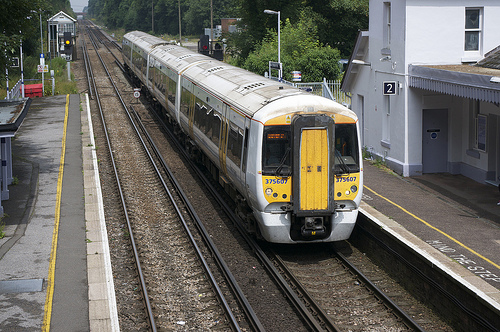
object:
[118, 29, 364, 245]
incoming train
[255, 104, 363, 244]
front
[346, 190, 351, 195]
headlight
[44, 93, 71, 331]
line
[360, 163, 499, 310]
platform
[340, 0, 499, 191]
building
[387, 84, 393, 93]
number 2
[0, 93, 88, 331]
platform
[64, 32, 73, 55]
train signal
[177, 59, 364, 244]
train car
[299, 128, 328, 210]
door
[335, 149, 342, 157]
driver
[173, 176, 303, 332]
gravel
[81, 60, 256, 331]
tracks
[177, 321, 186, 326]
trash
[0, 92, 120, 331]
ground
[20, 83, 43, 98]
object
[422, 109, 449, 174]
door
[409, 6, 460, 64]
wall surface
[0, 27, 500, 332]
train station